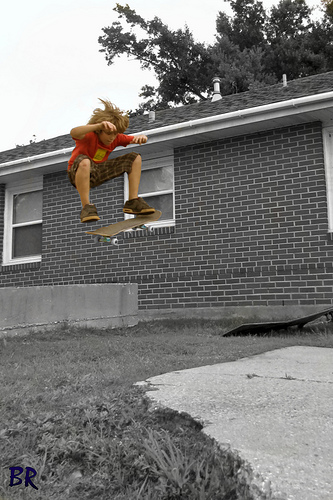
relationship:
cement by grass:
[124, 335, 332, 498] [1, 305, 332, 499]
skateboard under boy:
[84, 202, 164, 247] [57, 96, 162, 228]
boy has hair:
[57, 96, 162, 228] [81, 97, 131, 136]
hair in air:
[81, 97, 131, 136] [0, 0, 331, 145]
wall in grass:
[1, 281, 146, 340] [1, 305, 332, 499]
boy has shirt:
[57, 96, 162, 228] [62, 123, 131, 169]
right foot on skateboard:
[75, 202, 102, 228] [84, 202, 164, 247]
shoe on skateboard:
[120, 191, 158, 219] [84, 202, 164, 247]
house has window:
[0, 68, 332, 320] [0, 162, 58, 279]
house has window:
[0, 68, 332, 320] [114, 140, 185, 246]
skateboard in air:
[84, 202, 164, 247] [0, 0, 331, 145]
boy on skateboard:
[57, 96, 162, 228] [84, 202, 164, 247]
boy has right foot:
[57, 96, 162, 228] [75, 202, 102, 228]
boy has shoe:
[57, 96, 162, 228] [120, 191, 158, 219]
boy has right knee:
[57, 96, 162, 228] [73, 156, 95, 175]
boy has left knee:
[57, 96, 162, 228] [121, 148, 147, 172]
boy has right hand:
[57, 96, 162, 228] [98, 117, 120, 136]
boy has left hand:
[57, 96, 162, 228] [128, 130, 152, 147]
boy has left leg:
[57, 96, 162, 228] [100, 147, 150, 209]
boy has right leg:
[57, 96, 162, 228] [67, 150, 99, 208]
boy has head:
[57, 96, 162, 228] [84, 104, 135, 145]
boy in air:
[57, 96, 162, 228] [0, 0, 331, 145]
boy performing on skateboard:
[57, 96, 162, 228] [84, 202, 164, 247]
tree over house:
[91, 1, 332, 121] [0, 68, 332, 320]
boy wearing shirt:
[57, 96, 162, 228] [62, 123, 131, 169]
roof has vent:
[1, 70, 332, 176] [278, 63, 299, 93]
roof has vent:
[1, 70, 332, 176] [207, 73, 225, 109]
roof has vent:
[1, 70, 332, 176] [136, 103, 163, 131]